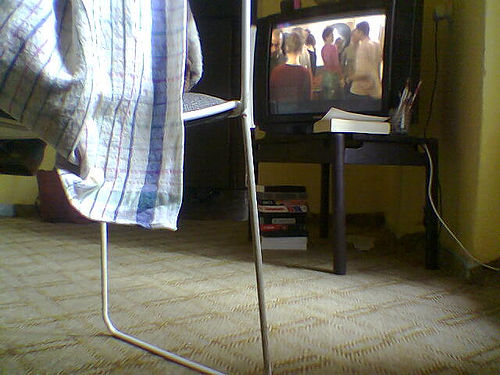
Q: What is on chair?
A: White frame.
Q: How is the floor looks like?
A: Brown and tan.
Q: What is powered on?
A: TV.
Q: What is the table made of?
A: Wood.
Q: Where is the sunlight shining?
A: Floor.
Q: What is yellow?
A: Walls.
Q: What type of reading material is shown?
A: Book.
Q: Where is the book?
A: In front of the TV.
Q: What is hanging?
A: A blue and white towel.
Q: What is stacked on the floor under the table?
A: Movie cases.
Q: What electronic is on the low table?
A: Television.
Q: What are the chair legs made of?
A: Metal.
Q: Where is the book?
A: Table.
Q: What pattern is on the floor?
A: Rectangles.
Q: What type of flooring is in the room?
A: Carpet.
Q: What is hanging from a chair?
A: A shirt.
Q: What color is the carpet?
A: Brown.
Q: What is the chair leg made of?
A: Steel.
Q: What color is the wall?
A: Yellow.